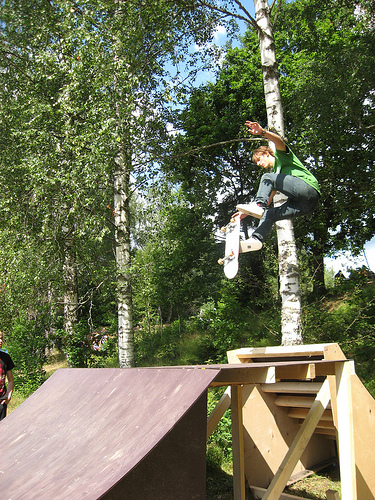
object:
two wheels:
[221, 219, 240, 237]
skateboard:
[224, 213, 241, 278]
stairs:
[222, 343, 363, 366]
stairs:
[251, 380, 365, 402]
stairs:
[271, 400, 367, 422]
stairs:
[294, 414, 367, 456]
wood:
[226, 337, 375, 497]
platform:
[149, 362, 341, 394]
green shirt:
[267, 143, 323, 198]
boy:
[0, 331, 15, 423]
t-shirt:
[0, 341, 18, 406]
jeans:
[252, 174, 322, 237]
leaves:
[95, 60, 115, 85]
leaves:
[0, 0, 122, 255]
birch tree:
[41, 0, 92, 370]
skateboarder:
[237, 121, 322, 252]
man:
[216, 121, 321, 261]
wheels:
[229, 251, 234, 257]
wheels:
[231, 218, 236, 223]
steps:
[262, 380, 336, 474]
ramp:
[226, 342, 373, 498]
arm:
[261, 130, 293, 150]